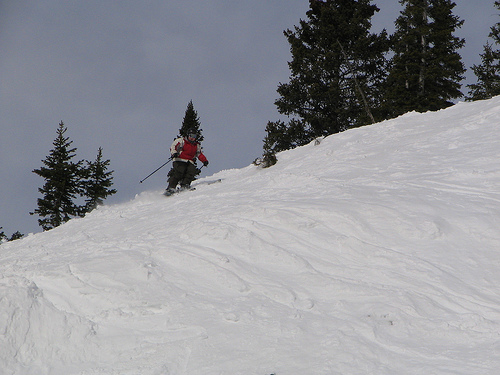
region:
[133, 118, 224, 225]
man skiing down mountain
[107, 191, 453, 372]
mountain covered in snow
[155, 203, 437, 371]
mountain covered in white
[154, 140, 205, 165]
red and white snow jacket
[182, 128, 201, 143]
black snow hat on head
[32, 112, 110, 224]
green trees in background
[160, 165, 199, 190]
black snow pants on man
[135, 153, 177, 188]
black ski pole in hand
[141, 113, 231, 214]
man skiing on side of mountain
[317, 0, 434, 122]
green tree covered in leaves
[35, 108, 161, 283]
pine trees on a hill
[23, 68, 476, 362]
a snow covered hill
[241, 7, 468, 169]
pine trees on a snow hill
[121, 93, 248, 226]
a skier on a snow hill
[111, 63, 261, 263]
a skier going down hill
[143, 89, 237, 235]
person wearing a red and white snow coat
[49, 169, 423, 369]
tracks in the snow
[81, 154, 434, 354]
ski tracks in the snow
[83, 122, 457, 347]
tracks in the snow from skiers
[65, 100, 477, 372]
a white snow hill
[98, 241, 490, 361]
Ski tracks on a hill.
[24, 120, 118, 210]
Evergreen trees growing up the side of the mountain.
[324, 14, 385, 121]
A tall tree falling over.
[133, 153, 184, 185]
The ski balancers held by a man on skis.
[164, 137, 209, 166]
A skier wearing a red and white jacket.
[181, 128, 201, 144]
Man skier wearing a ski hat.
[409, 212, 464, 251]
A swirl ski track pattern.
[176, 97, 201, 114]
The tip of an evergreen tree.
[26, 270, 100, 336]
Snowdrifts on a mountain.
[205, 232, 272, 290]
white snow on hill side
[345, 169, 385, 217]
white snow on hill side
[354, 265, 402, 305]
white snow on hill side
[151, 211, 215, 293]
white snow on hill side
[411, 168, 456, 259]
white snow on hill side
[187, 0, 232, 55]
white clouds in blue sky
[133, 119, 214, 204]
A skier skiing down a slope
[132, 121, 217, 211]
A skier skiing down a slope